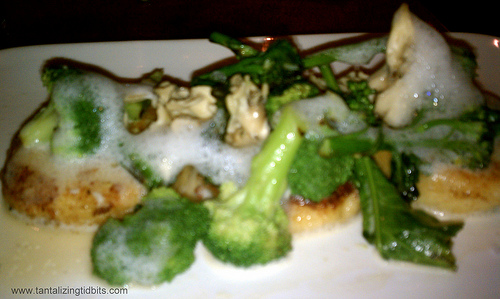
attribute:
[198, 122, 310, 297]
broccoli — green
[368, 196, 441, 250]
leaf — green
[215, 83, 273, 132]
mushroom — brown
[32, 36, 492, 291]
plate — white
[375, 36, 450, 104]
dressing — white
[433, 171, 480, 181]
sauce — brown, yellow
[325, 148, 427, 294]
spinach — vein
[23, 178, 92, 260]
food — blurred, reflecting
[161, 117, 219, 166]
foam — white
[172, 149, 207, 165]
vegetable — tan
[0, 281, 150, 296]
address — web, black, website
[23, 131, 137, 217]
scallop — brown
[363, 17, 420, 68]
chunk — white